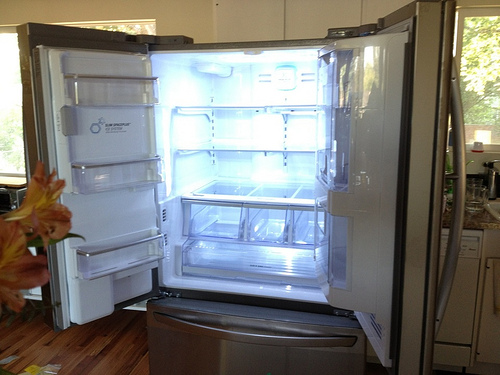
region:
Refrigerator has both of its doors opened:
[12, 24, 497, 373]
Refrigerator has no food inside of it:
[146, 39, 358, 326]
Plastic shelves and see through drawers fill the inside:
[160, 61, 320, 287]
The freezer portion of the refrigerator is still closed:
[150, 295, 395, 365]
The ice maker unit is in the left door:
[41, 86, 191, 176]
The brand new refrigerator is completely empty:
[11, 12, 495, 373]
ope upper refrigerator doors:
[21, 0, 473, 355]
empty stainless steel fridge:
[14, 11, 466, 372]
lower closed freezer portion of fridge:
[139, 302, 376, 363]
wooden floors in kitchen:
[5, 314, 152, 372]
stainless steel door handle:
[436, 58, 472, 336]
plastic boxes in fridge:
[181, 200, 323, 249]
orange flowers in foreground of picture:
[7, 159, 88, 314]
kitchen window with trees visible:
[456, 15, 498, 157]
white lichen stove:
[433, 233, 499, 364]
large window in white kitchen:
[3, 25, 159, 182]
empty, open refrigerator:
[9, 0, 473, 371]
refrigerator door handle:
[431, 50, 472, 346]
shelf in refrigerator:
[170, 70, 330, 124]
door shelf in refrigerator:
[59, 58, 162, 126]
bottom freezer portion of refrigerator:
[137, 298, 369, 373]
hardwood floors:
[1, 297, 150, 372]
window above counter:
[444, 11, 499, 159]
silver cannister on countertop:
[481, 163, 499, 207]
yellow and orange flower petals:
[0, 158, 87, 322]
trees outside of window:
[466, 24, 498, 122]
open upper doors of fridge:
[13, 0, 484, 374]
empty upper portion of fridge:
[28, 19, 408, 341]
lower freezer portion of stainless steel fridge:
[128, 314, 366, 366]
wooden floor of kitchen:
[5, 303, 152, 373]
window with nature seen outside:
[457, 17, 494, 137]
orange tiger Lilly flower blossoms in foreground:
[3, 155, 81, 308]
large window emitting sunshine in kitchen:
[4, 28, 138, 173]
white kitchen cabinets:
[439, 158, 499, 360]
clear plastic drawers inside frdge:
[178, 180, 314, 243]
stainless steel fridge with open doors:
[7, 14, 484, 367]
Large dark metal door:
[13, 18, 168, 335]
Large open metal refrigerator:
[16, 0, 468, 374]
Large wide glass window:
[0, 33, 27, 178]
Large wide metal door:
[144, 301, 373, 373]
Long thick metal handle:
[157, 309, 363, 354]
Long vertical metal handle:
[436, 57, 466, 347]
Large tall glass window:
[451, 16, 499, 148]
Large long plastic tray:
[58, 71, 160, 111]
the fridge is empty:
[168, 59, 318, 284]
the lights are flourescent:
[203, 69, 324, 129]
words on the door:
[87, 113, 146, 145]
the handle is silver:
[437, 64, 455, 324]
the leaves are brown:
[6, 182, 66, 323]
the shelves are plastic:
[189, 156, 307, 203]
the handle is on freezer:
[174, 315, 346, 369]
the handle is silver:
[172, 314, 340, 357]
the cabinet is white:
[457, 235, 491, 367]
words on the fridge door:
[90, 122, 134, 142]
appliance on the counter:
[465, 157, 492, 222]